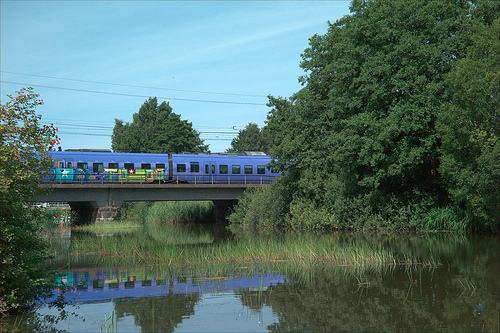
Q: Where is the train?
A: On a bridge.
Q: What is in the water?
A: Reflection.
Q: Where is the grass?
A: Next to the water.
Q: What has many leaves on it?
A: The tree.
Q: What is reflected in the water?
A: Train.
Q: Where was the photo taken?
A: Outside somewhere.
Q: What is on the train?
A: Windows.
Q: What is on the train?
A: Art.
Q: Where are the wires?
A: Above the train.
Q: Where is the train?
A: On the bridge.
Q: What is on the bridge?
A: A train.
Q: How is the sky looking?
A: Blue.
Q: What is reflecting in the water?
A: Train.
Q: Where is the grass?
A: In the water.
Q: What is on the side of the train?
A: Graffiti.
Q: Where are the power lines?
A: Above the train.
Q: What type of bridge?
A: Metal.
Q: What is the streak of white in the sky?
A: Clouds.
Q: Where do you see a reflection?
A: In the water.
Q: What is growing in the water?
A: Grass.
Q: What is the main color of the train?
A: Blue.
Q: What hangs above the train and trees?
A: Power lines.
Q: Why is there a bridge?
A: So the train can pass over the water.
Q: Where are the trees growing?
A: On the shore.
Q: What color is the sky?
A: Blue.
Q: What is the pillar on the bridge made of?
A: Brick.